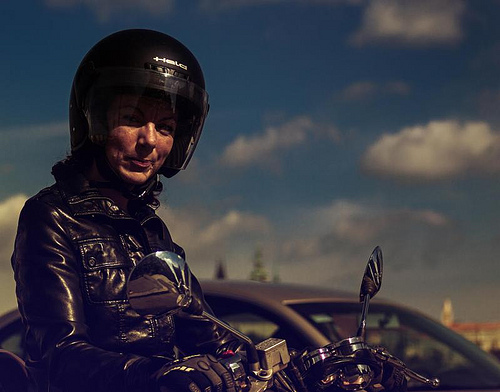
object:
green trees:
[215, 243, 282, 284]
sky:
[0, 0, 499, 324]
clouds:
[348, 0, 468, 51]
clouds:
[359, 119, 499, 185]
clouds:
[216, 115, 351, 181]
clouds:
[154, 199, 500, 284]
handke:
[346, 322, 373, 367]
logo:
[153, 56, 188, 70]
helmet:
[69, 29, 210, 180]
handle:
[356, 293, 370, 336]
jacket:
[10, 177, 247, 392]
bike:
[0, 246, 439, 392]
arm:
[11, 210, 144, 387]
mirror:
[125, 250, 195, 319]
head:
[70, 29, 210, 188]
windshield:
[288, 302, 499, 392]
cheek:
[107, 124, 140, 150]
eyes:
[125, 114, 173, 132]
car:
[0, 278, 499, 392]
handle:
[361, 346, 407, 376]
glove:
[156, 354, 246, 392]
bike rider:
[10, 28, 240, 392]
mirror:
[126, 246, 382, 319]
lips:
[128, 155, 151, 168]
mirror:
[358, 245, 384, 301]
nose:
[136, 111, 162, 148]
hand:
[142, 353, 246, 392]